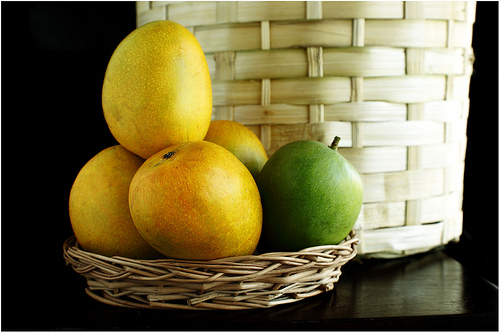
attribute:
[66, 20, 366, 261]
mangos — balanced, plentiful, green, yellow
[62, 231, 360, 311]
basket — brown, holding fruit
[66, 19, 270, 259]
four mangos — ripe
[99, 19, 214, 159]
mango — on top, yellow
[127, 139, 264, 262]
mango — yellow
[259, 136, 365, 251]
mango — green, next to yellow ones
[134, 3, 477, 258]
basket — large, light, big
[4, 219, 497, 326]
table — shiny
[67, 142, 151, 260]
fruit — yellow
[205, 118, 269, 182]
mango — yellow